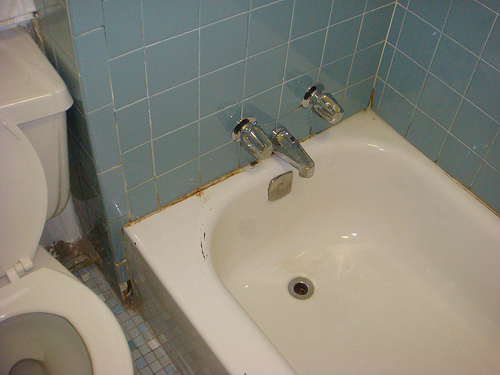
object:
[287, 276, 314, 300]
drain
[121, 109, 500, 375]
tub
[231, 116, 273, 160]
knob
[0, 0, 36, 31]
towel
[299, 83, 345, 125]
silver knob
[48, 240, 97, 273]
dirt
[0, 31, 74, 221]
white plastic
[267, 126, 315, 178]
spout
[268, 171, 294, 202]
patch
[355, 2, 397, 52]
tile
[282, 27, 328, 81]
tile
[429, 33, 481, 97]
tile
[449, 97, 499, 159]
tile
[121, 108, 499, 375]
bathtub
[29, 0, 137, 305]
wall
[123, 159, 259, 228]
stain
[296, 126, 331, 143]
stain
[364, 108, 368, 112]
stain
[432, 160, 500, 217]
stain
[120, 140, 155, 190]
tile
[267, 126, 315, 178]
faucet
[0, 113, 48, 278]
lid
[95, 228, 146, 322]
stains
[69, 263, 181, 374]
floor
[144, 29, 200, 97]
tile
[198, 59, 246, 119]
tile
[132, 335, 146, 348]
tile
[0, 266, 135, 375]
toilet bowl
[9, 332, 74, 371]
water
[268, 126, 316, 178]
shower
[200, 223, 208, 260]
dirt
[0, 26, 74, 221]
toilet tank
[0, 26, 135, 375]
toilet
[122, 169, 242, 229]
grout